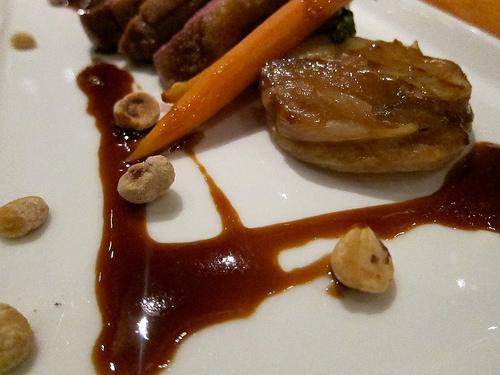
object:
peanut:
[117, 153, 176, 204]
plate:
[1, 0, 499, 373]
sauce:
[76, 57, 498, 373]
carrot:
[123, 0, 353, 164]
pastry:
[259, 35, 476, 174]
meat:
[152, 0, 292, 91]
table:
[418, 0, 499, 39]